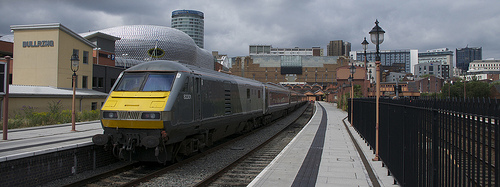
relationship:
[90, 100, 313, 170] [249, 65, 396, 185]
track on ground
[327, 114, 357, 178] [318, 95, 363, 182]
brick in sidewalk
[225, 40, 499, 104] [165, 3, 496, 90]
background buildings in background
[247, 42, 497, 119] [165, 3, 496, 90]
background buildings in background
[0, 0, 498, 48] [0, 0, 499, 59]
cloud in sky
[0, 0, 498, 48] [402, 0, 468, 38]
cloud in sky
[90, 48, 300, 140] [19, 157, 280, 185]
train on tracks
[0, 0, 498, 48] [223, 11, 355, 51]
cloud in sky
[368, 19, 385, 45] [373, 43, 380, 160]
lamp on pole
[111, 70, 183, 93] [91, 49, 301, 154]
window on train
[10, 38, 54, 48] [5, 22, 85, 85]
letters on building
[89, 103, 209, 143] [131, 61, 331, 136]
headlights on train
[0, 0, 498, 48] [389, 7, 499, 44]
cloud in sky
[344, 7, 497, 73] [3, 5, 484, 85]
cloud in sky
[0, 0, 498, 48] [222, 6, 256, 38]
cloud in sky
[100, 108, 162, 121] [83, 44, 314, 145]
headlights on train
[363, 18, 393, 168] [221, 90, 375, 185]
pole in ground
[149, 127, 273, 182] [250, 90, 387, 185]
gravel on ground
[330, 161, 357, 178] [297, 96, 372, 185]
brick on sidewalk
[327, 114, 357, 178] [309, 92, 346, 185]
brick on sidewalk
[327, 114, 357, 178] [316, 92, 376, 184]
brick on sidewalk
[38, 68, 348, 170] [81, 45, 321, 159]
track under train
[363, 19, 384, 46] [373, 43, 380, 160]
lamp on pole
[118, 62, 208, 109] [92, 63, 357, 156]
window on train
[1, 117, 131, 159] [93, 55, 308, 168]
platform next to train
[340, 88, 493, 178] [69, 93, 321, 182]
fence along railroad tracks